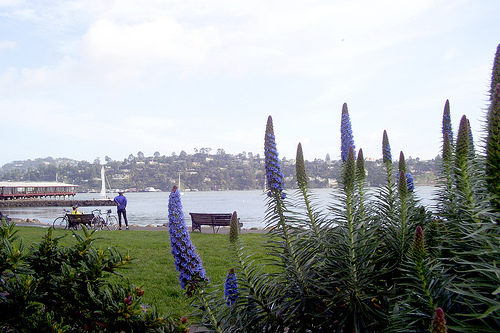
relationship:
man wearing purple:
[104, 171, 163, 280] [116, 199, 127, 205]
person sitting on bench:
[71, 205, 85, 227] [60, 209, 97, 229]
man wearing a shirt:
[113, 192, 130, 231] [112, 194, 129, 210]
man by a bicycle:
[113, 192, 130, 231] [87, 203, 122, 230]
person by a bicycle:
[70, 199, 82, 225] [48, 204, 73, 226]